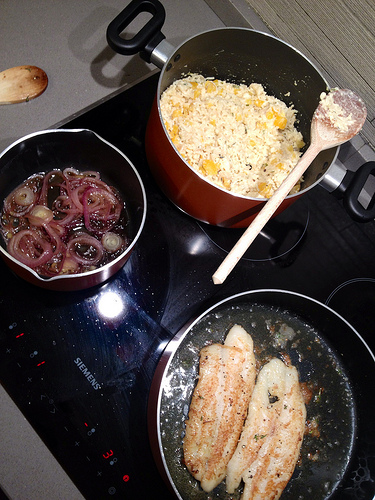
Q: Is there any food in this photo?
A: Yes, there is food.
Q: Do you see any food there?
A: Yes, there is food.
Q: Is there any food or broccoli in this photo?
A: Yes, there is food.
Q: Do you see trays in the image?
A: No, there are no trays.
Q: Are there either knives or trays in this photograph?
A: No, there are no trays or knives.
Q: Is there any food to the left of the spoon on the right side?
A: Yes, there is food to the left of the spoon.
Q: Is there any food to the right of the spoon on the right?
A: No, the food is to the left of the spoon.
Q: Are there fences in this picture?
A: No, there are no fences.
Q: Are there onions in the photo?
A: Yes, there are onions.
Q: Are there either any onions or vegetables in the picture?
A: Yes, there are onions.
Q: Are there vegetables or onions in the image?
A: Yes, there are onions.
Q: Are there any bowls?
A: No, there are no bowls.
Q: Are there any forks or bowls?
A: No, there are no bowls or forks.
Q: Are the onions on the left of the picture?
A: Yes, the onions are on the left of the image.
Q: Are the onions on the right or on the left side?
A: The onions are on the left of the image.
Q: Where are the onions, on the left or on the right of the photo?
A: The onions are on the left of the image.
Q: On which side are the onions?
A: The onions are on the left of the image.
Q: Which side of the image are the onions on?
A: The onions are on the left of the image.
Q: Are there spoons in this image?
A: Yes, there is a spoon.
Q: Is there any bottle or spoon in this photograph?
A: Yes, there is a spoon.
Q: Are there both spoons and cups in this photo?
A: No, there is a spoon but no cups.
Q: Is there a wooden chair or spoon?
A: Yes, there is a wood spoon.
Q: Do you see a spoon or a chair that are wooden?
A: Yes, the spoon is wooden.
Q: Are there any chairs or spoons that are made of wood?
A: Yes, the spoon is made of wood.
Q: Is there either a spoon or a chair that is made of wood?
A: Yes, the spoon is made of wood.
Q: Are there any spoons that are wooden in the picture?
A: Yes, there is a wood spoon.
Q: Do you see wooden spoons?
A: Yes, there is a wood spoon.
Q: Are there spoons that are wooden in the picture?
A: Yes, there is a wood spoon.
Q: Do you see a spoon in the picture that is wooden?
A: Yes, there is a spoon that is wooden.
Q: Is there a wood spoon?
A: Yes, there is a spoon that is made of wood.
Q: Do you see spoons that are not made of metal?
A: Yes, there is a spoon that is made of wood.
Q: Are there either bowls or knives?
A: No, there are no bowls or knives.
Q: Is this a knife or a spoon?
A: This is a spoon.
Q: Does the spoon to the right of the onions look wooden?
A: Yes, the spoon is wooden.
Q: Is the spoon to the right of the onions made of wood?
A: Yes, the spoon is made of wood.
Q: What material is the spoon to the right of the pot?
A: The spoon is made of wood.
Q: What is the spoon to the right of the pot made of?
A: The spoon is made of wood.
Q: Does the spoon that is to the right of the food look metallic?
A: No, the spoon is wooden.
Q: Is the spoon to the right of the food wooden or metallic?
A: The spoon is wooden.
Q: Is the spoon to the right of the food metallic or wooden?
A: The spoon is wooden.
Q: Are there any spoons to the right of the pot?
A: Yes, there is a spoon to the right of the pot.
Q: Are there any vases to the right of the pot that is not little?
A: No, there is a spoon to the right of the pot.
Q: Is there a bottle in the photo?
A: No, there are no bottles.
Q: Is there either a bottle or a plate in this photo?
A: No, there are no bottles or plates.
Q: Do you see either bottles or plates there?
A: No, there are no bottles or plates.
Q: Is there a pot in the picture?
A: Yes, there is a pot.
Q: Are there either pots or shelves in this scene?
A: Yes, there is a pot.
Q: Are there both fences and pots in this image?
A: No, there is a pot but no fences.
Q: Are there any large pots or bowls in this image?
A: Yes, there is a large pot.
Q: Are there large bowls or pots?
A: Yes, there is a large pot.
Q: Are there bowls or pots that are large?
A: Yes, the pot is large.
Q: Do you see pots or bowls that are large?
A: Yes, the pot is large.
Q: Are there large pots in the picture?
A: Yes, there is a large pot.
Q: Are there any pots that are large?
A: Yes, there is a pot that is large.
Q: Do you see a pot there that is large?
A: Yes, there is a pot that is large.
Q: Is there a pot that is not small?
A: Yes, there is a large pot.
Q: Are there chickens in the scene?
A: No, there are no chickens.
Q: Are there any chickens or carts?
A: No, there are no chickens or carts.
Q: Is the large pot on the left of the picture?
A: Yes, the pot is on the left of the image.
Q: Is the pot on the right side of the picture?
A: No, the pot is on the left of the image.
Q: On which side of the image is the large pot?
A: The pot is on the left of the image.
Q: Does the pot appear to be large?
A: Yes, the pot is large.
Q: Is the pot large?
A: Yes, the pot is large.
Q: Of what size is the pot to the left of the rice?
A: The pot is large.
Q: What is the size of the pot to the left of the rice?
A: The pot is large.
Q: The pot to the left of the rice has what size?
A: The pot is large.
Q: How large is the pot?
A: The pot is large.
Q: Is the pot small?
A: No, the pot is large.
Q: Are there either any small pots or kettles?
A: No, there is a pot but it is large.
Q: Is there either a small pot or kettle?
A: No, there is a pot but it is large.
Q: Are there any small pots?
A: No, there is a pot but it is large.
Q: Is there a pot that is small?
A: No, there is a pot but it is large.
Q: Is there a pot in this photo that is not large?
A: No, there is a pot but it is large.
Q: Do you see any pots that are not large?
A: No, there is a pot but it is large.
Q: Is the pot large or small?
A: The pot is large.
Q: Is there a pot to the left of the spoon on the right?
A: Yes, there is a pot to the left of the spoon.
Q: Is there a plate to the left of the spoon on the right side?
A: No, there is a pot to the left of the spoon.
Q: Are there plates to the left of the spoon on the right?
A: No, there is a pot to the left of the spoon.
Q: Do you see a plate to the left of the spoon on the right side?
A: No, there is a pot to the left of the spoon.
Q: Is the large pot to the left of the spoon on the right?
A: Yes, the pot is to the left of the spoon.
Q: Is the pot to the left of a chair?
A: No, the pot is to the left of the spoon.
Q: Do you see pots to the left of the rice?
A: Yes, there is a pot to the left of the rice.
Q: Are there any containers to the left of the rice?
A: No, there is a pot to the left of the rice.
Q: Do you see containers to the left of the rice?
A: No, there is a pot to the left of the rice.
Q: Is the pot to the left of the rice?
A: Yes, the pot is to the left of the rice.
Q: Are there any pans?
A: Yes, there is a pan.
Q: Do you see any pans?
A: Yes, there is a pan.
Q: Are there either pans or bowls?
A: Yes, there is a pan.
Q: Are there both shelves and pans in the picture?
A: No, there is a pan but no shelves.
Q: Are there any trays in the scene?
A: No, there are no trays.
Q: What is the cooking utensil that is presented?
A: The cooking utensil is a pan.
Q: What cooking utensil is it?
A: The cooking utensil is a pan.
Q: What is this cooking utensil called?
A: That is a pan.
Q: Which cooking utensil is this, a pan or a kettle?
A: That is a pan.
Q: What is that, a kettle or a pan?
A: That is a pan.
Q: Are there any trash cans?
A: No, there are no trash cans.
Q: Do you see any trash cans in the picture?
A: No, there are no trash cans.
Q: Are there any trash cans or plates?
A: No, there are no trash cans or plates.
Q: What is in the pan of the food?
A: The fish is in the pan.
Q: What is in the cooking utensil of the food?
A: The fish is in the pan.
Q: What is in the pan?
A: The fish is in the pan.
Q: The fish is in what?
A: The fish is in the pan.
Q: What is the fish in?
A: The fish is in the pan.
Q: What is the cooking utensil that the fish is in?
A: The cooking utensil is a pan.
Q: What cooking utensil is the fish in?
A: The fish is in the pan.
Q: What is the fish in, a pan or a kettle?
A: The fish is in a pan.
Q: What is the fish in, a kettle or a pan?
A: The fish is in a pan.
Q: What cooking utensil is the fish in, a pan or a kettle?
A: The fish is in a pan.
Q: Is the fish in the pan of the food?
A: Yes, the fish is in the pan.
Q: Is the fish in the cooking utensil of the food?
A: Yes, the fish is in the pan.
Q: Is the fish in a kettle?
A: No, the fish is in the pan.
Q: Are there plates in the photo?
A: No, there are no plates.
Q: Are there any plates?
A: No, there are no plates.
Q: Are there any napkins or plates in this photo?
A: No, there are no plates or napkins.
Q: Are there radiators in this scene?
A: No, there are no radiators.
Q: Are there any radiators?
A: No, there are no radiators.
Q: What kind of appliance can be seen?
A: The appliance is a stove.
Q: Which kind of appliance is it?
A: The appliance is a stove.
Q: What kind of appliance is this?
A: That is a stove.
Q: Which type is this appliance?
A: That is a stove.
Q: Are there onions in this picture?
A: Yes, there are onions.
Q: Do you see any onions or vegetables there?
A: Yes, there are onions.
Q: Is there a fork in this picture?
A: No, there are no forks.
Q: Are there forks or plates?
A: No, there are no forks or plates.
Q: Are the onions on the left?
A: Yes, the onions are on the left of the image.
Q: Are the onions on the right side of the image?
A: No, the onions are on the left of the image.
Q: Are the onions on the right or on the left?
A: The onions are on the left of the image.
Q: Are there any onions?
A: Yes, there are onions.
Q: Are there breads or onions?
A: Yes, there are onions.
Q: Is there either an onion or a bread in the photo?
A: Yes, there are onions.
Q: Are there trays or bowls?
A: No, there are no bowls or trays.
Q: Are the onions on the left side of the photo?
A: Yes, the onions are on the left of the image.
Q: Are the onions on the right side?
A: No, the onions are on the left of the image.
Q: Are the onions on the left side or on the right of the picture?
A: The onions are on the left of the image.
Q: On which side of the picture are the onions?
A: The onions are on the left of the image.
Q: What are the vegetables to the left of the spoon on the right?
A: The vegetables are onions.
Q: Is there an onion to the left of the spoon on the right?
A: Yes, there are onions to the left of the spoon.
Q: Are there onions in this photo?
A: Yes, there are onions.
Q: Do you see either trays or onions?
A: Yes, there are onions.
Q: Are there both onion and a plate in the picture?
A: No, there are onions but no plates.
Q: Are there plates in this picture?
A: No, there are no plates.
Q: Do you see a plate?
A: No, there are no plates.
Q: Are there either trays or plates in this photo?
A: No, there are no plates or trays.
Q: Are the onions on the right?
A: No, the onions are on the left of the image.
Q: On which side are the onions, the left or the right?
A: The onions are on the left of the image.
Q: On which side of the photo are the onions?
A: The onions are on the left of the image.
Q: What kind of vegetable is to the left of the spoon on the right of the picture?
A: The vegetables are onions.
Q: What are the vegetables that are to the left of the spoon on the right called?
A: The vegetables are onions.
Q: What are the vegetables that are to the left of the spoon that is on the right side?
A: The vegetables are onions.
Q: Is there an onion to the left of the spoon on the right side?
A: Yes, there are onions to the left of the spoon.